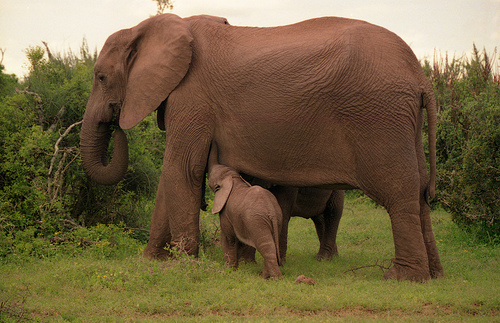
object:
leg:
[348, 106, 429, 272]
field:
[0, 196, 500, 323]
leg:
[415, 137, 440, 268]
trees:
[0, 125, 80, 248]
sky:
[0, 0, 497, 79]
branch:
[342, 257, 393, 274]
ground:
[4, 276, 497, 323]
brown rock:
[294, 274, 315, 285]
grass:
[1, 181, 500, 323]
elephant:
[239, 172, 345, 265]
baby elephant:
[207, 138, 283, 279]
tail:
[420, 79, 436, 198]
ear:
[118, 13, 194, 130]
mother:
[78, 13, 444, 284]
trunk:
[79, 106, 129, 186]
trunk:
[209, 140, 219, 169]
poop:
[295, 274, 315, 285]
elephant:
[79, 13, 444, 284]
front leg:
[160, 112, 214, 257]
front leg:
[146, 174, 174, 249]